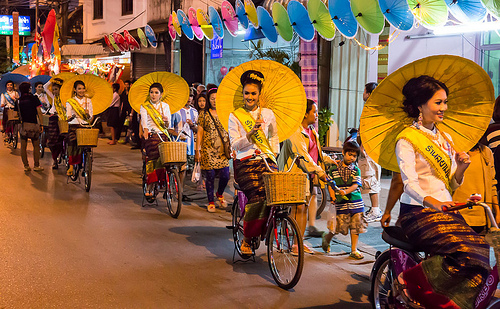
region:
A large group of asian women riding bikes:
[24, 55, 498, 291]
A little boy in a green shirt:
[325, 140, 357, 267]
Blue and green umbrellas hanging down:
[249, 6, 486, 40]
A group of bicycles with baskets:
[3, 117, 316, 307]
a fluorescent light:
[413, 25, 498, 38]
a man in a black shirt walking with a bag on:
[16, 79, 46, 179]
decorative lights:
[21, 52, 71, 68]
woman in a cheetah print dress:
[196, 87, 233, 202]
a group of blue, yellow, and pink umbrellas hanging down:
[161, 8, 252, 40]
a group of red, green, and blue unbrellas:
[94, 20, 169, 54]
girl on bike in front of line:
[359, 55, 497, 307]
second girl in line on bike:
[215, 60, 316, 289]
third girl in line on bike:
[126, 70, 191, 216]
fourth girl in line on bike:
[57, 73, 115, 195]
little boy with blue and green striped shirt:
[326, 142, 365, 265]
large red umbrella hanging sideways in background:
[36, 7, 56, 62]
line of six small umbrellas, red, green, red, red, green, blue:
[98, 23, 160, 55]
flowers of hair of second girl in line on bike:
[243, 67, 272, 86]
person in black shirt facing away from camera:
[11, 80, 45, 181]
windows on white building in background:
[78, 0, 138, 23]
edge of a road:
[86, 208, 127, 259]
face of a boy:
[346, 150, 353, 160]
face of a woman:
[433, 90, 448, 102]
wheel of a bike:
[268, 245, 284, 268]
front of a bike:
[176, 192, 196, 196]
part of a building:
[91, 1, 113, 22]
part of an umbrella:
[377, 108, 384, 116]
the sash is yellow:
[232, 108, 271, 153]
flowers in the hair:
[243, 67, 266, 89]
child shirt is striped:
[330, 157, 365, 217]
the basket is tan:
[261, 178, 304, 269]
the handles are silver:
[252, 150, 305, 170]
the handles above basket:
[240, 147, 314, 207]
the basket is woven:
[260, 165, 305, 205]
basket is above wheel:
[257, 172, 314, 290]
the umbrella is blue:
[285, 3, 315, 49]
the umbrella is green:
[350, 2, 386, 37]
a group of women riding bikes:
[43, 72, 479, 269]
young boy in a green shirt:
[327, 139, 382, 256]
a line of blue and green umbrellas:
[257, 0, 498, 33]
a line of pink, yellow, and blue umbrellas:
[163, 7, 266, 43]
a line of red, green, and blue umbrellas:
[96, 25, 168, 57]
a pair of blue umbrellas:
[6, 67, 50, 87]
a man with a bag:
[11, 84, 45, 171]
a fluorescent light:
[421, 21, 495, 33]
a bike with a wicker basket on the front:
[221, 156, 340, 281]